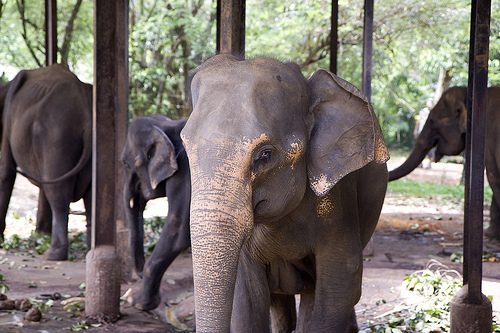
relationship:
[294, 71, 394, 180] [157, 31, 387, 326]
ear of elephant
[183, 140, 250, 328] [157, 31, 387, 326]
trunk of elephant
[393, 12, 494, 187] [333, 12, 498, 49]
tree has leaves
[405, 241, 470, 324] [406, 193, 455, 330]
leaves on ground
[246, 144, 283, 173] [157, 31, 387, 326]
eye of elephant